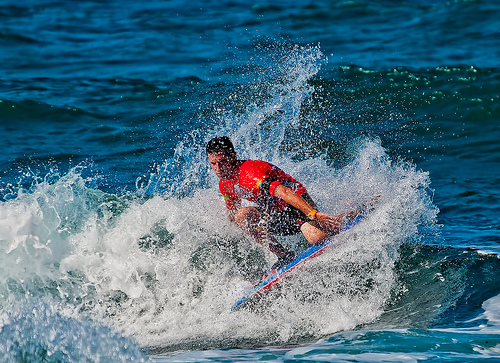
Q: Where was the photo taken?
A: It was taken at the ocean.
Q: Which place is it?
A: It is an ocean.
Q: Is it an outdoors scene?
A: Yes, it is outdoors.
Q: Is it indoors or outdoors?
A: It is outdoors.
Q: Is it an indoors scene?
A: No, it is outdoors.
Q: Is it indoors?
A: No, it is outdoors.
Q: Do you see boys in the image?
A: No, there are no boys.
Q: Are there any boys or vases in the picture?
A: No, there are no boys or vases.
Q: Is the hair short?
A: Yes, the hair is short.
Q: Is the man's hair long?
A: No, the hair is short.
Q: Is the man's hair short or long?
A: The hair is short.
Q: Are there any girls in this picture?
A: No, there are no girls.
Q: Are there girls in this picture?
A: No, there are no girls.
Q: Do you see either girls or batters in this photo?
A: No, there are no girls or batters.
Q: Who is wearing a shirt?
A: The man is wearing a shirt.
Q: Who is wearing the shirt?
A: The man is wearing a shirt.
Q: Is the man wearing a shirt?
A: Yes, the man is wearing a shirt.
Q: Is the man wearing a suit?
A: No, the man is wearing a shirt.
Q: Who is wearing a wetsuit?
A: The man is wearing a wetsuit.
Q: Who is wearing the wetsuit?
A: The man is wearing a wetsuit.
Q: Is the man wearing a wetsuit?
A: Yes, the man is wearing a wetsuit.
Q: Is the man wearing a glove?
A: No, the man is wearing a wetsuit.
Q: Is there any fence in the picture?
A: No, there are no fences.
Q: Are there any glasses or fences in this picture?
A: No, there are no fences or glasses.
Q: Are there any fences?
A: No, there are no fences.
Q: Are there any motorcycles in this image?
A: No, there are no motorcycles.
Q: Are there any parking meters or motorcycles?
A: No, there are no motorcycles or parking meters.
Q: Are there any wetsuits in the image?
A: Yes, there is a wetsuit.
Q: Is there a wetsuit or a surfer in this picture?
A: Yes, there is a wetsuit.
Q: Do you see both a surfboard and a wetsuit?
A: Yes, there are both a wetsuit and a surfboard.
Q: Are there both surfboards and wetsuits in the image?
A: Yes, there are both a wetsuit and a surfboard.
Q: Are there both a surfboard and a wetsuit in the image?
A: Yes, there are both a wetsuit and a surfboard.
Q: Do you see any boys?
A: No, there are no boys.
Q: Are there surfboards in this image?
A: Yes, there is a surfboard.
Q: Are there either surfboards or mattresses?
A: Yes, there is a surfboard.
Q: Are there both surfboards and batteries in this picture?
A: No, there is a surfboard but no batteries.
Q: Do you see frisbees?
A: No, there are no frisbees.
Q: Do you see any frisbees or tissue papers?
A: No, there are no frisbees or tissue papers.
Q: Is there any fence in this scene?
A: No, there are no fences.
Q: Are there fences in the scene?
A: No, there are no fences.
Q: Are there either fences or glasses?
A: No, there are no fences or glasses.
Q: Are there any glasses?
A: No, there are no glasses.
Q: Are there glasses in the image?
A: No, there are no glasses.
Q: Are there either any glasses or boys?
A: No, there are no glasses or boys.